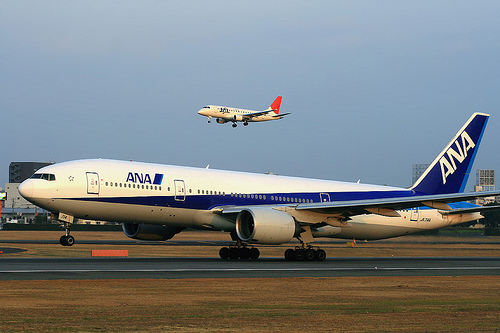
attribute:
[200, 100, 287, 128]
plane — landing, orange, taking off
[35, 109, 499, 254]
white — blue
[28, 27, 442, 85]
sky — blue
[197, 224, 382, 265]
landing gear — down